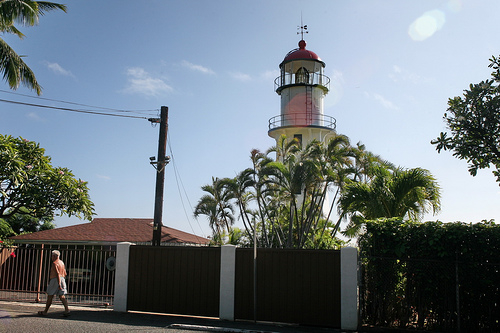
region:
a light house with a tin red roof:
[268, 11, 339, 249]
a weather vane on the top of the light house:
[295, 13, 309, 41]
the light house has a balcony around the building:
[268, 111, 337, 129]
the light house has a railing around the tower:
[273, 59, 330, 89]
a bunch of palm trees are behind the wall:
[193, 133, 440, 253]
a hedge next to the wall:
[358, 217, 499, 332]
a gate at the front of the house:
[1, 236, 119, 308]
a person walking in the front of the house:
[37, 248, 70, 315]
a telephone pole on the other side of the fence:
[150, 106, 169, 245]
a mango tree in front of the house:
[1, 133, 97, 247]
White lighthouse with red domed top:
[256, 35, 351, 241]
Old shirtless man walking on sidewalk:
[35, 241, 75, 321]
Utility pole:
[132, 95, 177, 241]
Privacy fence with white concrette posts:
[111, 240, 358, 330]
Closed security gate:
[0, 240, 115, 310]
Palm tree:
[0, 0, 70, 95]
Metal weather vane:
[290, 5, 305, 35]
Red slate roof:
[0, 215, 220, 240]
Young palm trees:
[195, 130, 440, 240]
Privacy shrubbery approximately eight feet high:
[360, 216, 496, 323]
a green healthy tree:
[194, 185, 226, 250]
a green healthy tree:
[207, 168, 238, 239]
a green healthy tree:
[228, 167, 252, 247]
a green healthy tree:
[248, 150, 269, 256]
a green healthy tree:
[266, 144, 301, 242]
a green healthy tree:
[293, 134, 348, 242]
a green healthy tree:
[331, 159, 439, 224]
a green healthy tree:
[1, 127, 94, 240]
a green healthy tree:
[0, 0, 53, 105]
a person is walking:
[41, 242, 76, 317]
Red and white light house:
[262, 11, 351, 219]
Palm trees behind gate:
[185, 136, 437, 243]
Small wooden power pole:
[144, 100, 181, 242]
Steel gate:
[2, 230, 115, 307]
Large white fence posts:
[104, 233, 371, 329]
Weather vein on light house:
[288, 8, 317, 52]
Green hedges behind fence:
[362, 219, 499, 318]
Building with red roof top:
[11, 196, 230, 321]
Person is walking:
[35, 244, 79, 326]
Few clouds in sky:
[26, 39, 493, 118]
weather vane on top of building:
[253, 22, 368, 75]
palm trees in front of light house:
[186, 133, 471, 297]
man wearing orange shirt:
[34, 236, 92, 331]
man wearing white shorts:
[27, 202, 79, 330]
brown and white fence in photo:
[103, 239, 290, 329]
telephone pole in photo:
[99, 97, 195, 322]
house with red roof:
[23, 201, 233, 330]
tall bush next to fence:
[337, 201, 498, 322]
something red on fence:
[6, 242, 26, 281]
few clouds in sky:
[41, 42, 268, 144]